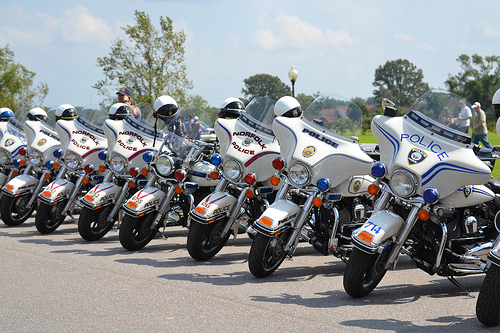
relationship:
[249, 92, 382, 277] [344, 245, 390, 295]
motorcycle has a tire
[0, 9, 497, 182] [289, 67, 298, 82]
park has a light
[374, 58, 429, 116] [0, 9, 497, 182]
tree in park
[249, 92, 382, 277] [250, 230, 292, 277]
motorcycle has a front wheel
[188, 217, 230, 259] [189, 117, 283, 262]
wheel in front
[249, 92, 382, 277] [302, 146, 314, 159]
motorcycle has a symbol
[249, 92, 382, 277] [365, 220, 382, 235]
motorcycle has a number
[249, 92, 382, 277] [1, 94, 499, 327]
motorcycle are in a row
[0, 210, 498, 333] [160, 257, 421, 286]
ground has a shadow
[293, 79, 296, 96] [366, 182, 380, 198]
post has a light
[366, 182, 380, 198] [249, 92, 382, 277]
light near motorcycle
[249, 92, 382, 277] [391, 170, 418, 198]
motorcycle has a headlight